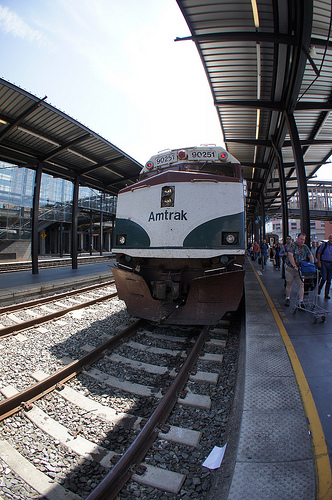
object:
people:
[245, 223, 330, 312]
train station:
[4, 7, 326, 498]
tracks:
[7, 272, 242, 494]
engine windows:
[131, 152, 247, 193]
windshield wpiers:
[197, 160, 211, 169]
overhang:
[179, 2, 329, 231]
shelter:
[0, 74, 115, 193]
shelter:
[171, 0, 322, 141]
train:
[104, 139, 253, 332]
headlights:
[111, 231, 240, 247]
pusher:
[115, 264, 242, 328]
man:
[284, 230, 315, 306]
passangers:
[254, 225, 331, 320]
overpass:
[43, 180, 331, 220]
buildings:
[269, 188, 331, 260]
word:
[141, 207, 189, 225]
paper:
[265, 260, 275, 267]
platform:
[211, 332, 279, 497]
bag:
[298, 257, 319, 281]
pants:
[282, 265, 292, 292]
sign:
[39, 230, 51, 238]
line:
[275, 314, 331, 499]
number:
[189, 147, 199, 162]